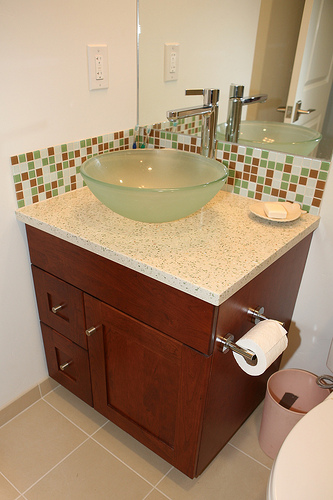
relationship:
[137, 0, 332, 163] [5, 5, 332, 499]
mirror in bathroom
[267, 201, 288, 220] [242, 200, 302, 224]
soap in dish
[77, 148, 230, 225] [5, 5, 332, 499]
sink in bathroom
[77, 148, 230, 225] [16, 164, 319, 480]
bowl on vanity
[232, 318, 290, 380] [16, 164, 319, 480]
paper mounted vanity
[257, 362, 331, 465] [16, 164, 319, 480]
trash between vanity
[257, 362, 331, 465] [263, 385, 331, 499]
trash between toilet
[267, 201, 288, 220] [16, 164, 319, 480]
soap on vanity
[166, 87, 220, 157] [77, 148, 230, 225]
faucet over bowl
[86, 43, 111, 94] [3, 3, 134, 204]
outlet on wall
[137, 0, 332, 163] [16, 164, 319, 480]
mirror above vanity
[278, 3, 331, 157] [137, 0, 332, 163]
reflection in mirror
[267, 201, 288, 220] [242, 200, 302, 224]
soap on dish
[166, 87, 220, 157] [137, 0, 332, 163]
faucet attached mirror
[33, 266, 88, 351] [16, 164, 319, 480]
drawer on vanity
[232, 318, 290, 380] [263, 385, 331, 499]
paper next toilet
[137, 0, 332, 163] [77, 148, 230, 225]
mirror behind sink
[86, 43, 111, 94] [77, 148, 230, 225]
outlet next sink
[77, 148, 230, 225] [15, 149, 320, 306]
sink on countertop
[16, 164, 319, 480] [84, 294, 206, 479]
vanity has door